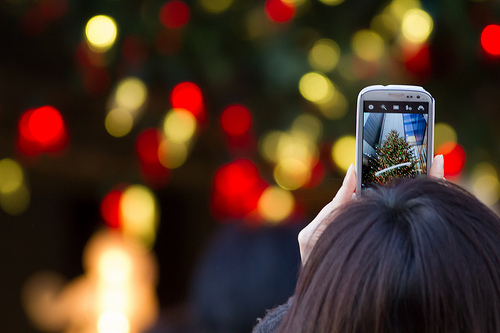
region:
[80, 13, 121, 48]
A yellow shiny light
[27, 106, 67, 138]
A red shiny light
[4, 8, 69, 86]
A black dark surface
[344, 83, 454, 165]
A white digital phone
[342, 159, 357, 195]
Long brown colored fingers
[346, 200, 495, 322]
Long lustrous black hair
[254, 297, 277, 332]
A grey colored sweater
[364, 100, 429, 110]
A digital phone menu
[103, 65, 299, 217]
Beautiful multi colored lights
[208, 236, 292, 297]
A navy blue surface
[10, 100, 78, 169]
red light on a tree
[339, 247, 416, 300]
dark brown hair on a head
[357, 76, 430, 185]
a silver cell phone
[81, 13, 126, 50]
white light on a Christmas tree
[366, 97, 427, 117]
control panel on the phone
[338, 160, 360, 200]
a finger holding the phone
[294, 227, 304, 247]
knuckle on a hand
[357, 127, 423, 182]
the picture of a Christmas tree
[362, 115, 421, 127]
a high rise building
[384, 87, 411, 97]
logo on the phone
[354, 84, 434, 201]
a silver edged smart phone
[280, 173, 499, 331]
the top of someone's head of dark hair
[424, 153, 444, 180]
a single fingertip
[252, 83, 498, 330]
a woman taking a photo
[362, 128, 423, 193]
a decorated Christmas tree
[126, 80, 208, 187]
a group of yellow and red Christmas lights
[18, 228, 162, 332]
a blurry yellow person shape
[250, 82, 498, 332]
a woman trying to take a picture of what she is looking at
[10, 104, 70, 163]
a jumble of red circles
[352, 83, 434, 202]
an Android smart phone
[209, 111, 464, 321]
back of girl's head showing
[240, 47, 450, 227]
girl holding a phone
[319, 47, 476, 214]
the phone is silver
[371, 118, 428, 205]
trees on the phone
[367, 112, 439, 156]
buildings on the phone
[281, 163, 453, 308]
girl's hair is brown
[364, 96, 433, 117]
picture tools on the phone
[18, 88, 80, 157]
the lights are red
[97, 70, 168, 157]
the lights are yellow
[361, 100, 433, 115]
picture tools are white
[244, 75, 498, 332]
person holding phone up to take photo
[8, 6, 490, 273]
red and yellow lights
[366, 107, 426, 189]
phone screen with picture on it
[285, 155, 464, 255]
hands of person holding phone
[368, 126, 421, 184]
christmas tree on phone's screen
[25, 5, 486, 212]
red sparkly light in the distance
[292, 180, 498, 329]
dark hair of woman holding phone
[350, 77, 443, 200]
white phone being held by woman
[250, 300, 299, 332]
black sleeve of woman holding phone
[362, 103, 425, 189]
screen of white phone